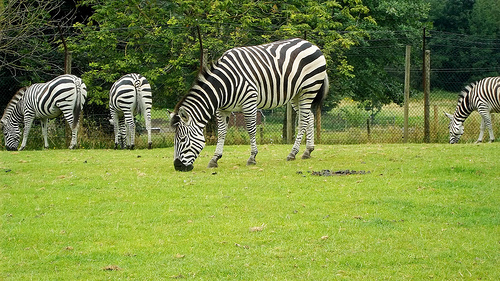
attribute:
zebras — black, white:
[2, 36, 497, 171]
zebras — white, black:
[81, 32, 424, 194]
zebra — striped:
[150, 14, 353, 207]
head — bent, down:
[157, 105, 217, 197]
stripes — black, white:
[228, 36, 320, 94]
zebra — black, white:
[129, 69, 419, 202]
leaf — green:
[468, 39, 479, 49]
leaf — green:
[364, 12, 381, 29]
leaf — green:
[277, 19, 298, 34]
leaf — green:
[162, 11, 179, 31]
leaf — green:
[70, 19, 87, 33]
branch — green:
[45, 1, 67, 18]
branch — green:
[48, 58, 68, 79]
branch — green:
[0, 43, 27, 63]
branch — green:
[4, 0, 25, 20]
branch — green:
[48, 2, 72, 16]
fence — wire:
[337, 71, 432, 146]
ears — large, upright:
[158, 104, 187, 125]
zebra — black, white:
[170, 31, 329, 180]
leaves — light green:
[224, 5, 324, 30]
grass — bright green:
[321, 185, 339, 224]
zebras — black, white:
[46, 30, 383, 197]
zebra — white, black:
[132, 42, 389, 197]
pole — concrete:
[419, 47, 436, 141]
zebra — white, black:
[94, 67, 175, 151]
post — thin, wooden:
[398, 42, 413, 146]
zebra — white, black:
[147, 32, 369, 188]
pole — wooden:
[399, 39, 435, 141]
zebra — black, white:
[162, 31, 332, 172]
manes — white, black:
[163, 76, 202, 116]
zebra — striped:
[155, 34, 344, 209]